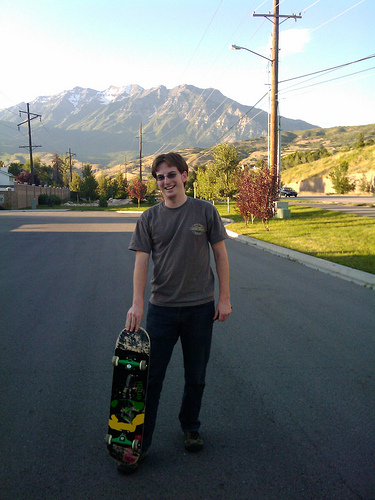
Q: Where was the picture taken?
A: In a street.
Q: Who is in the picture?
A: A man.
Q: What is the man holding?
A: A skateboard.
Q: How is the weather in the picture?
A: Sunny.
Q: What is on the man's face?
A: Sunglasses.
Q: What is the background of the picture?
A: A mountain.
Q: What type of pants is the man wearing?
A: Jeans.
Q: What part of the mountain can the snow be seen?
A: On peaks.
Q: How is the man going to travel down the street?
A: Skateboard.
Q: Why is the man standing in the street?
A: He is going skateboarding.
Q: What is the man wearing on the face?
A: Transitional glasses.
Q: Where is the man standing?
A: Street.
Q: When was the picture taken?
A: During a sunny day.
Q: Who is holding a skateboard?
A: A man in a brown shirt.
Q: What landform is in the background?
A: Mountains.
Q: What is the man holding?
A: Skateboard.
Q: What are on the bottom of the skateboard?
A: Wheels.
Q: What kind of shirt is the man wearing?
A: T-shirt.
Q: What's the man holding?
A: Skateboard.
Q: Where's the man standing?
A: Street.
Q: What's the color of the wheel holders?
A: Green.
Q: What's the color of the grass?
A: Green.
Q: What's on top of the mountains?
A: Snow.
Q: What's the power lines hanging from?
A: Tall poles.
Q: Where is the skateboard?
A: Right hand.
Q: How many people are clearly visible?
A: 1.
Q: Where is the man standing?
A: In the street.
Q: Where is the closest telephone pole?
A: On the right.